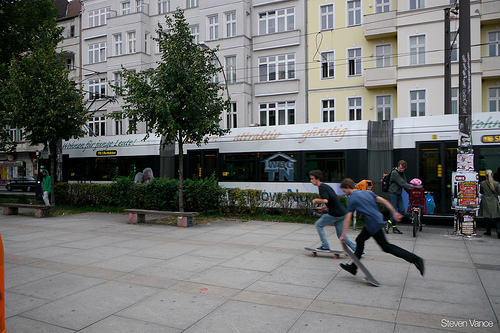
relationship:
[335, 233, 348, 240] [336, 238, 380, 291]
hand holding skateboard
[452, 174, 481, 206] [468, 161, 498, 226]
sign by woman